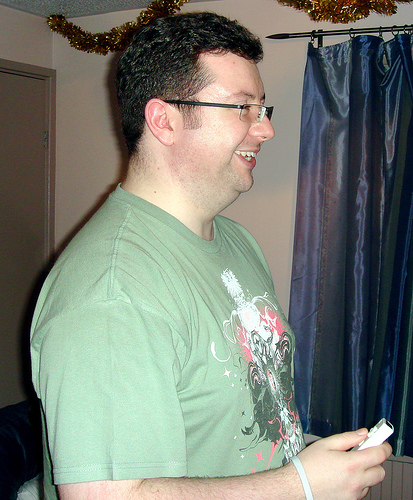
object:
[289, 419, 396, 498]
hand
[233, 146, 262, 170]
mouth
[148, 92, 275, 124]
black glasses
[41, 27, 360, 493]
man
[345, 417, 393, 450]
controller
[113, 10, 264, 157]
hair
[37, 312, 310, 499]
arm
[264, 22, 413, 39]
curtain rod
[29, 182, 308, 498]
shirt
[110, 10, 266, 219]
head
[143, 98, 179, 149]
ear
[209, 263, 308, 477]
design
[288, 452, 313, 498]
strap